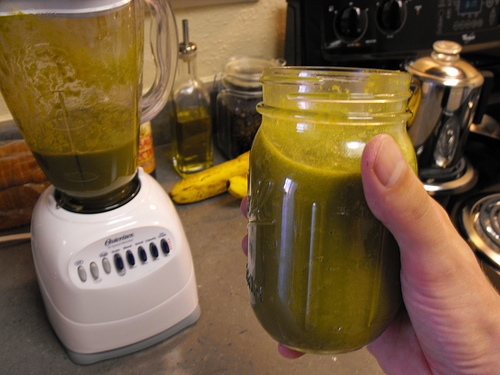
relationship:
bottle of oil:
[170, 16, 214, 176] [179, 107, 216, 171]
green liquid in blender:
[28, 135, 145, 208] [0, 2, 203, 367]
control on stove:
[337, 3, 372, 47] [303, 7, 485, 69]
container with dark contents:
[213, 50, 287, 185] [218, 93, 250, 139]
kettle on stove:
[404, 46, 486, 223] [1, 97, 498, 373]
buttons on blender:
[71, 234, 172, 285] [0, 2, 203, 367]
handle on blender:
[138, 1, 187, 133] [4, 16, 294, 364]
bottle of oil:
[170, 16, 216, 180] [179, 105, 216, 171]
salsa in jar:
[248, 132, 417, 352] [247, 68, 422, 356]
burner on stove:
[456, 185, 498, 269] [287, 0, 499, 292]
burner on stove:
[410, 162, 481, 192] [287, 0, 499, 292]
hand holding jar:
[240, 135, 499, 374] [206, 51, 443, 373]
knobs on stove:
[326, 0, 434, 32] [287, 0, 499, 292]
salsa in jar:
[248, 127, 417, 351] [247, 68, 422, 356]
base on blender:
[29, 186, 200, 364] [0, 2, 203, 367]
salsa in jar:
[248, 127, 417, 351] [206, 51, 443, 373]